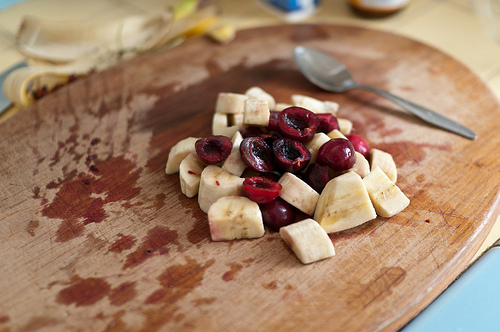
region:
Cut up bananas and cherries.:
[130, 61, 416, 256]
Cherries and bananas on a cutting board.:
[47, 76, 419, 298]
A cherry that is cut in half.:
[272, 135, 310, 170]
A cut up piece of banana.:
[272, 220, 335, 268]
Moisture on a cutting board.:
[27, 165, 117, 246]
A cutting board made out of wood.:
[4, 21, 496, 327]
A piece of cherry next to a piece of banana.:
[226, 170, 321, 203]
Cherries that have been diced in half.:
[243, 101, 318, 171]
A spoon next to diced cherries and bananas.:
[140, 27, 496, 267]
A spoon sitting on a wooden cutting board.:
[9, 33, 491, 329]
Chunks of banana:
[163, 80, 428, 242]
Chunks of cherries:
[174, 86, 408, 252]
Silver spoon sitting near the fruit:
[294, 38, 482, 149]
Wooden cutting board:
[0, 43, 499, 325]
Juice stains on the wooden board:
[24, 113, 196, 302]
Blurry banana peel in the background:
[2, 3, 212, 106]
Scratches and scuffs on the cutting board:
[0, 22, 495, 289]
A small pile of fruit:
[147, 77, 417, 252]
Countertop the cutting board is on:
[3, 6, 496, 325]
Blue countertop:
[388, 244, 497, 329]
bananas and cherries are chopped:
[187, 85, 394, 239]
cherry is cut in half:
[255, 132, 321, 174]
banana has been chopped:
[210, 191, 272, 241]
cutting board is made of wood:
[36, 65, 428, 277]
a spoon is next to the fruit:
[277, 33, 494, 161]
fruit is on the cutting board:
[26, 14, 495, 276]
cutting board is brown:
[35, 112, 302, 316]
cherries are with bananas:
[203, 95, 375, 223]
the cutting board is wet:
[67, 93, 294, 243]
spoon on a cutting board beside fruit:
[163, 39, 483, 241]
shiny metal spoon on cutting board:
[293, 45, 478, 142]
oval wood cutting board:
[0, 30, 499, 330]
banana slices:
[209, 196, 264, 238]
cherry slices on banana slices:
[242, 136, 279, 168]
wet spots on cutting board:
[56, 275, 111, 307]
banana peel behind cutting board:
[8, 6, 241, 106]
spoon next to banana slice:
[294, 46, 478, 146]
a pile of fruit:
[167, 86, 407, 258]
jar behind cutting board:
[347, 0, 412, 19]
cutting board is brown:
[1, 23, 498, 330]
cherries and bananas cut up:
[188, 93, 390, 249]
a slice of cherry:
[279, 108, 313, 138]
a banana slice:
[276, 220, 339, 262]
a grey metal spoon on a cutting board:
[289, 33, 476, 148]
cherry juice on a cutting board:
[33, 149, 167, 283]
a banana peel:
[10, 6, 224, 91]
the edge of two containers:
[265, 0, 424, 27]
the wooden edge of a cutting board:
[404, 247, 492, 319]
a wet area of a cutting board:
[141, 69, 203, 119]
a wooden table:
[435, 6, 494, 42]